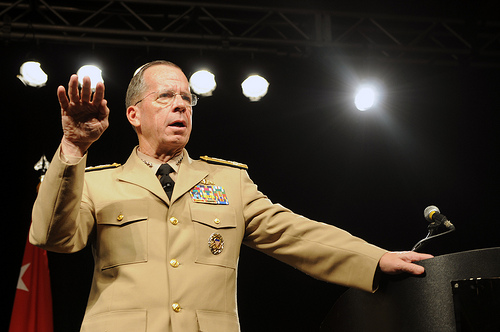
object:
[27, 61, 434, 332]
man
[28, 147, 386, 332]
uniform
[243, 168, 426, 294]
arm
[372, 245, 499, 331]
podium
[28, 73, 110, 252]
arm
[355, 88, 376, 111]
lights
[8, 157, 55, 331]
flag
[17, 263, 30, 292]
design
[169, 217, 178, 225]
buttons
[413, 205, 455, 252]
microphone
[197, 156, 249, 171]
epaulets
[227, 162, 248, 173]
shoulders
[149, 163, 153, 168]
stars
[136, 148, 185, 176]
collar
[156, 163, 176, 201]
tie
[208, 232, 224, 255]
insignia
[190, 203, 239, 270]
pocket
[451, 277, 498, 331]
speaker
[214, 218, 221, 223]
button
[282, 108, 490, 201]
blackdrop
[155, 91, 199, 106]
glasses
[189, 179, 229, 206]
medals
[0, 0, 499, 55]
railing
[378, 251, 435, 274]
hand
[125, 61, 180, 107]
hair